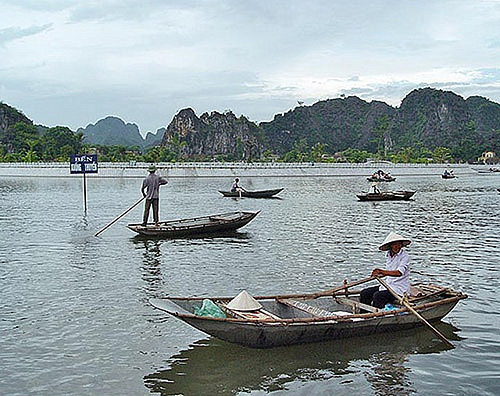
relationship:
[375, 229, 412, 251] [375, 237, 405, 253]
white hat on head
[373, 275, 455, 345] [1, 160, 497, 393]
oar in water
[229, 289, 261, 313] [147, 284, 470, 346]
hat on boat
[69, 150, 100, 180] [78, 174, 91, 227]
blue sign on post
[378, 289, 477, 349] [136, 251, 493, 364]
wooden paddle to move boat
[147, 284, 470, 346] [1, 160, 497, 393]
boat in water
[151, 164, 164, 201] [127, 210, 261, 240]
person standing on boat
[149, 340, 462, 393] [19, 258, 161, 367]
shadow on water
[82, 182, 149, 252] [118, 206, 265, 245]
pole used to push boat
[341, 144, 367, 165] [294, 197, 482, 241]
tree by side of water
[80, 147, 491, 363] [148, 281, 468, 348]
fishermen in boats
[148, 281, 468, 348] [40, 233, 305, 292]
boats on water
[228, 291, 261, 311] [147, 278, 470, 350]
hat in a boat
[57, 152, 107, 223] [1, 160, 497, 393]
sign in water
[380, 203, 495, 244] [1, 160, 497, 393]
ripples in water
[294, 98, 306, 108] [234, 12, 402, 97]
bird in sky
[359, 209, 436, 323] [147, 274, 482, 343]
man sailing in boat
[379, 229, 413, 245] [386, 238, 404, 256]
hat on head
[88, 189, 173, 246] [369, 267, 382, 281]
oar in hand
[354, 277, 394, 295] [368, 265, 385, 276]
oars ends in hands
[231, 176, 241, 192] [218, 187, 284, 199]
person rowing a boat